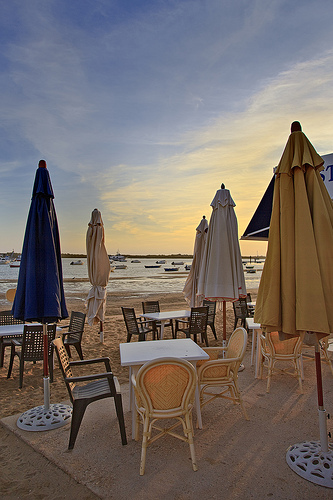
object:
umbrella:
[8, 155, 70, 328]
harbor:
[0, 255, 265, 294]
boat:
[145, 264, 162, 269]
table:
[119, 338, 211, 369]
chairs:
[197, 326, 250, 426]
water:
[0, 253, 267, 283]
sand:
[0, 288, 263, 500]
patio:
[0, 349, 330, 499]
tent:
[236, 155, 332, 246]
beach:
[2, 288, 332, 500]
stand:
[285, 336, 333, 492]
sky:
[0, 2, 332, 254]